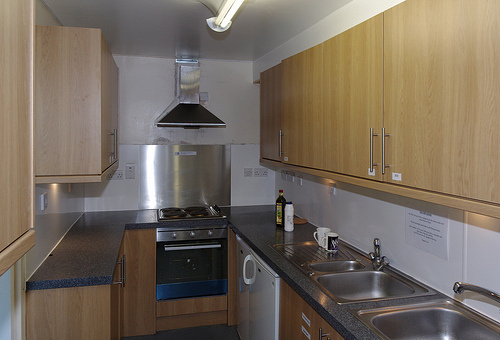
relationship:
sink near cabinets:
[321, 264, 492, 339] [255, 4, 498, 222]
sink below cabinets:
[321, 264, 492, 339] [255, 4, 498, 222]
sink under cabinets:
[321, 264, 492, 339] [255, 4, 498, 222]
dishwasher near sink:
[232, 239, 280, 339] [321, 264, 492, 339]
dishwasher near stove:
[232, 239, 280, 339] [156, 200, 232, 297]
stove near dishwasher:
[156, 200, 232, 297] [232, 239, 280, 339]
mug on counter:
[311, 224, 334, 247] [224, 204, 498, 338]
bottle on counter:
[274, 186, 284, 230] [224, 204, 498, 338]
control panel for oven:
[155, 224, 228, 242] [152, 220, 231, 301]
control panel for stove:
[155, 224, 228, 242] [157, 205, 221, 224]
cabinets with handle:
[255, 4, 498, 222] [366, 124, 388, 175]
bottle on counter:
[272, 188, 289, 228] [224, 204, 498, 338]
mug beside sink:
[313, 227, 332, 247] [309, 254, 435, 303]